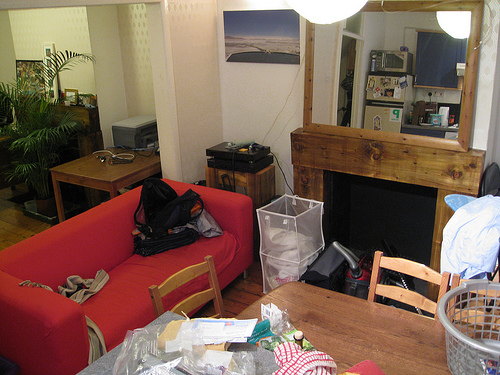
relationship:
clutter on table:
[112, 303, 335, 374] [225, 281, 494, 372]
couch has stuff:
[1, 171, 254, 374] [130, 177, 214, 258]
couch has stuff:
[1, 171, 254, 374] [20, 261, 109, 366]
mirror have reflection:
[306, 0, 484, 156] [331, 10, 470, 142]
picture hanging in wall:
[224, 9, 301, 65] [3, 3, 499, 197]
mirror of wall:
[306, 0, 484, 156] [3, 3, 499, 197]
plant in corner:
[0, 44, 95, 199] [0, 6, 96, 214]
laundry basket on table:
[437, 279, 499, 374] [225, 281, 494, 372]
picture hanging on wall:
[224, 9, 301, 65] [3, 3, 499, 197]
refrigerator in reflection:
[362, 72, 411, 135] [331, 10, 470, 142]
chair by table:
[368, 250, 448, 311] [225, 281, 494, 372]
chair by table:
[150, 256, 227, 322] [225, 281, 494, 372]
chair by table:
[448, 276, 499, 327] [225, 281, 494, 372]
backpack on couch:
[130, 177, 214, 258] [1, 171, 254, 374]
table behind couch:
[47, 145, 163, 223] [1, 171, 254, 374]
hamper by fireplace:
[258, 188, 325, 296] [290, 125, 490, 317]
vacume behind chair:
[332, 236, 408, 307] [368, 250, 448, 311]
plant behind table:
[0, 44, 95, 199] [47, 145, 163, 223]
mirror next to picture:
[306, 0, 484, 156] [224, 9, 301, 65]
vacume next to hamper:
[332, 236, 408, 307] [258, 188, 325, 296]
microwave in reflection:
[369, 50, 414, 77] [331, 10, 470, 142]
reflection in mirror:
[331, 10, 470, 142] [306, 0, 484, 156]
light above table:
[284, 4, 371, 27] [225, 281, 494, 372]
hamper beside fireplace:
[258, 188, 325, 296] [290, 125, 490, 317]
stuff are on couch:
[130, 177, 214, 258] [1, 171, 254, 374]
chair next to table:
[368, 250, 448, 311] [225, 281, 494, 372]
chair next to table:
[150, 256, 227, 322] [225, 281, 494, 372]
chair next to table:
[448, 276, 499, 327] [225, 281, 494, 372]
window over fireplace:
[411, 32, 469, 88] [290, 125, 490, 317]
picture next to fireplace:
[224, 9, 301, 65] [290, 125, 490, 317]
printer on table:
[111, 114, 156, 153] [47, 145, 163, 223]